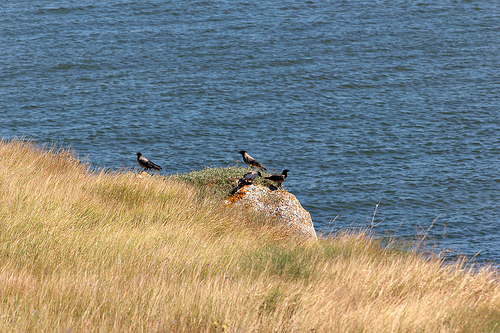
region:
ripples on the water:
[346, 20, 453, 104]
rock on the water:
[261, 186, 332, 238]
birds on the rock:
[222, 162, 295, 203]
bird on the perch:
[126, 129, 165, 202]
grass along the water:
[330, 232, 449, 288]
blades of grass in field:
[241, 245, 329, 287]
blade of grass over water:
[413, 205, 453, 251]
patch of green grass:
[232, 228, 360, 287]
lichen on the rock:
[219, 186, 254, 221]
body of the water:
[242, 96, 311, 153]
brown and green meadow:
[50, 224, 244, 319]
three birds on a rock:
[203, 132, 368, 234]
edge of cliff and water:
[319, 139, 493, 324]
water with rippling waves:
[322, 77, 494, 219]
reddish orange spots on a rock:
[218, 173, 335, 267]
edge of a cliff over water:
[31, 93, 132, 274]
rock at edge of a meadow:
[208, 175, 328, 291]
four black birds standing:
[108, 113, 330, 238]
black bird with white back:
[110, 130, 192, 205]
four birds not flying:
[113, 111, 353, 259]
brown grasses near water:
[12, 214, 214, 308]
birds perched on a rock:
[122, 133, 323, 200]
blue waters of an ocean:
[42, 12, 468, 124]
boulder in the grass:
[234, 192, 321, 237]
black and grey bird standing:
[129, 148, 165, 178]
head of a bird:
[237, 145, 249, 161]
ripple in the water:
[52, 57, 91, 71]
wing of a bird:
[266, 166, 284, 185]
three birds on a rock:
[219, 138, 305, 210]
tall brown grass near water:
[364, 198, 388, 223]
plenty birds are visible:
[112, 132, 346, 257]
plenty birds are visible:
[86, 91, 401, 288]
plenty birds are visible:
[77, 74, 305, 216]